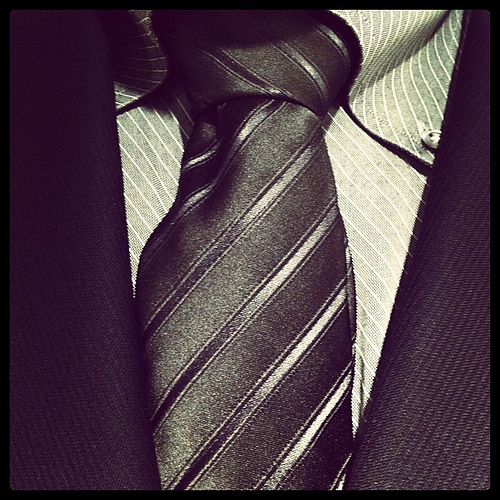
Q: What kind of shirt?
A: A gray pinstriped shirt.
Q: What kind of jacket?
A: Black suit jacket.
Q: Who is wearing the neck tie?
A: A man.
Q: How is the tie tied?
A: In a knot.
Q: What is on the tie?
A: Diagonal stripes.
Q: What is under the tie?
A: A gray shirt.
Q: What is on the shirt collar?
A: Buttons.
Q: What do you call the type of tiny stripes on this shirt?
A: Pinstripe.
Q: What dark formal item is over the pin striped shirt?
A: Suit jacket.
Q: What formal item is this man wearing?
A: Suit.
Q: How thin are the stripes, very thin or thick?
A: Thin.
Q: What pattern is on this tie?
A: Stripes.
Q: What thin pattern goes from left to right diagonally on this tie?
A: Stripes.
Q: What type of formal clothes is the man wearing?
A: Suit.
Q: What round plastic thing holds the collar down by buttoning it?
A: Button.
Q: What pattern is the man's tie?
A: Striped.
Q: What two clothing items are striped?
A: Tie and shirt.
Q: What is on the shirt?
A: A tie.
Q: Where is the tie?
A: On the person.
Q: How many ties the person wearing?
A: One.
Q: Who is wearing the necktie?
A: A man.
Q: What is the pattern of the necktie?
A: Stripes.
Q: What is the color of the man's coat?
A: Black.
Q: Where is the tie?
A: On the man's neck.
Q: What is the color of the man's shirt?
A: Gray.